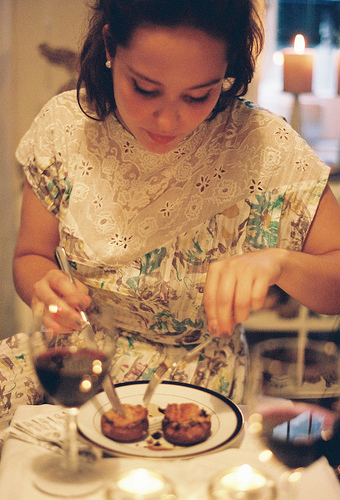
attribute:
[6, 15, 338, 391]
woman — floral, lacey, cutting, young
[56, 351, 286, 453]
plate — striped, white, black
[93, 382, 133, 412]
knife — held, silver, metal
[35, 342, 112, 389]
wine — red, here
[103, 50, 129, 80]
earring — small, pearl, white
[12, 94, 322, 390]
dress — skirt portion , pleats, green, brown, decorated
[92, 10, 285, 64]
hair — dark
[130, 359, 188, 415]
fork — held, metal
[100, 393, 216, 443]
food — cut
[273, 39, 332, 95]
candle — here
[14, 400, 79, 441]
napkin — folded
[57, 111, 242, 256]
fabric — white